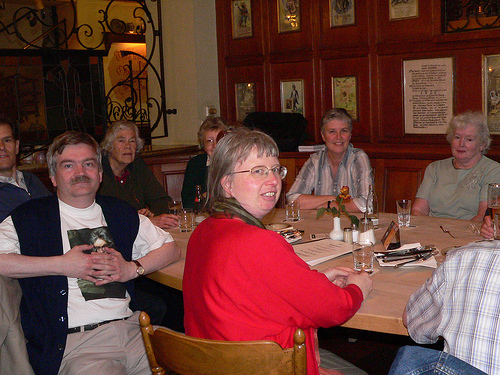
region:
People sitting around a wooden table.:
[2, 107, 497, 372]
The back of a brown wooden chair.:
[132, 307, 305, 372]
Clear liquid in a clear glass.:
[390, 192, 411, 228]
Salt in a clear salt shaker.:
[355, 210, 375, 245]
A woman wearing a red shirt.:
[181, 132, 364, 373]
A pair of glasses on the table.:
[432, 218, 479, 241]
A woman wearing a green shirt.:
[411, 110, 497, 216]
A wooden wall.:
[215, 0, 495, 211]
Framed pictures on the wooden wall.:
[220, 0, 498, 140]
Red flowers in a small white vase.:
[325, 184, 357, 243]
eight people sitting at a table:
[0, 105, 496, 372]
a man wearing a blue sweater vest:
[5, 188, 144, 371]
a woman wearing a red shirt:
[177, 215, 364, 373]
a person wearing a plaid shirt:
[405, 231, 497, 373]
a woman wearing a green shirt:
[415, 150, 499, 223]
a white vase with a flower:
[312, 184, 357, 240]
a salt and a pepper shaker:
[342, 221, 360, 244]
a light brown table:
[121, 198, 484, 337]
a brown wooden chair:
[135, 310, 307, 373]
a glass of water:
[393, 195, 410, 229]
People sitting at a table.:
[0, 103, 375, 373]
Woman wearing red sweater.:
[176, 215, 367, 373]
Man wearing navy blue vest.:
[7, 185, 139, 373]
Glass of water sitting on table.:
[393, 193, 419, 230]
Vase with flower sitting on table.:
[313, 183, 350, 245]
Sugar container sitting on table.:
[356, 213, 380, 248]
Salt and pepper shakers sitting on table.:
[342, 220, 362, 247]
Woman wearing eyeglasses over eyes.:
[225, 161, 290, 186]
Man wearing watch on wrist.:
[128, 252, 154, 279]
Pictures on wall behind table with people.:
[227, 59, 369, 121]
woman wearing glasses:
[236, 160, 301, 192]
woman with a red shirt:
[183, 232, 314, 356]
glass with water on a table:
[388, 189, 423, 246]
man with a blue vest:
[25, 205, 136, 311]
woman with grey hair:
[93, 115, 155, 160]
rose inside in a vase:
[318, 188, 356, 248]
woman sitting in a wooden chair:
[136, 280, 339, 371]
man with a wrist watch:
[121, 253, 151, 283]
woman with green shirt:
[115, 165, 167, 219]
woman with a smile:
[239, 183, 298, 215]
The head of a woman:
[198, 120, 294, 224]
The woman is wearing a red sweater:
[177, 211, 366, 373]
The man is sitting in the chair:
[3, 190, 164, 373]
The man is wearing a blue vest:
[14, 203, 155, 372]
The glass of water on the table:
[348, 240, 381, 276]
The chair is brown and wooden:
[121, 307, 323, 373]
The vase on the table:
[313, 182, 356, 242]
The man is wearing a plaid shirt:
[401, 225, 499, 373]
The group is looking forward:
[1, 100, 496, 371]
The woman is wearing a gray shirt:
[417, 158, 494, 223]